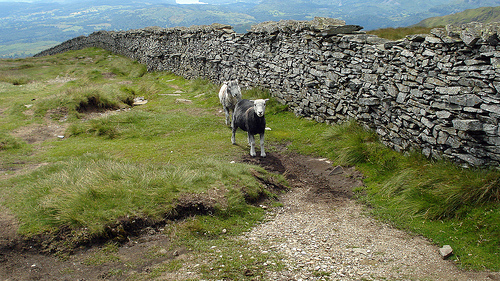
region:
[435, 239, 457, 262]
rock on the ground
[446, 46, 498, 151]
wall made of rocks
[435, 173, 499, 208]
tall green grass on ground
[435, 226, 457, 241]
short green grass on ground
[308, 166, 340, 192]
mud on the ground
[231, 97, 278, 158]
goat on the grass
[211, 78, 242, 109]
white goat near the wall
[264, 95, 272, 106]
left horn on the goat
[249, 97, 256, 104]
right horn on the goat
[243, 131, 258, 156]
the goat's right foot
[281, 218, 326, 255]
part of a ground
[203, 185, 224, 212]
part of a grass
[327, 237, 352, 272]
part of a ground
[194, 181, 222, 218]
part of a grass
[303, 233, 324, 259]
part of a ground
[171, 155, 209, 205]
part of a field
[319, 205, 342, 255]
part of a ground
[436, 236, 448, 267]
part of a stone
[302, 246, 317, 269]
part of a ground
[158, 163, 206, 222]
part of a grass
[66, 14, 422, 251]
Sheep standing next to a stone wall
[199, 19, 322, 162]
Two sheep standing next to a stone wall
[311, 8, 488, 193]
Fence made of a pile of rocks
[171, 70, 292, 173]
Two sheep standing on grass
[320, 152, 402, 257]
grass growing next to dirt and small rocks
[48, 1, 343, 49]
Hills behind a stone wall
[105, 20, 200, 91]
Fence made up of stones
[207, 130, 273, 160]
Sheep legs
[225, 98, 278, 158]
Black and white sheep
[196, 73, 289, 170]
A black and white sheep standing infront of a white sheep.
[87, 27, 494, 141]
Long tall rock wall.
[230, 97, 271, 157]
Black and white sheep.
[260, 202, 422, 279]
Gravel on the ground.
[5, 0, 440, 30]
Rolling hills in background.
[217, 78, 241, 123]
White sheep standing on grass.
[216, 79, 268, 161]
Two sheep facing camera.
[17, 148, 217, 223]
Patch of tall green grass.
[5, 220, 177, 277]
Dark brown dirt.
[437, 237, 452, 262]
Big rock on grass.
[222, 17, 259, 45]
A dip in the rock wall.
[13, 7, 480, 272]
two animals moving uphill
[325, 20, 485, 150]
wall made of stacked rocks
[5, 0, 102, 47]
features of a valley below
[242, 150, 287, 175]
shadow of the animal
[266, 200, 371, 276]
gravelly area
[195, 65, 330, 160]
sheep following a path next to a wall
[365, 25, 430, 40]
grass on the other side of the fence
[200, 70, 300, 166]
one sheep behind the other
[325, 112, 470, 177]
long grass growing at the base of the wall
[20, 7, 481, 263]
pastureland setting